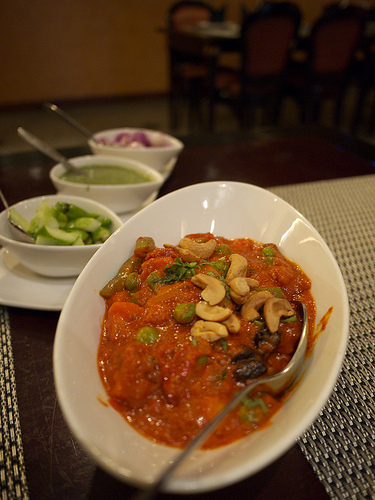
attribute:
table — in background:
[154, 2, 312, 129]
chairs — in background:
[162, 2, 373, 135]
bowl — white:
[48, 178, 343, 466]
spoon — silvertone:
[190, 268, 323, 465]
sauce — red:
[155, 350, 235, 415]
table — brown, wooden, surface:
[10, 150, 374, 477]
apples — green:
[6, 196, 113, 245]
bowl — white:
[0, 194, 125, 275]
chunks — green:
[16, 206, 111, 240]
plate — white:
[1, 244, 77, 307]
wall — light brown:
[0, 0, 163, 101]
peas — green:
[123, 273, 158, 291]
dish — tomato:
[149, 272, 247, 328]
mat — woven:
[213, 174, 365, 396]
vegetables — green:
[104, 235, 162, 298]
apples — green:
[21, 197, 92, 245]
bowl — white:
[16, 154, 370, 478]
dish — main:
[41, 175, 326, 470]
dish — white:
[148, 182, 314, 287]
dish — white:
[0, 243, 95, 308]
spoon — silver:
[136, 297, 317, 490]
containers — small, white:
[7, 115, 195, 281]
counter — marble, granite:
[23, 393, 57, 462]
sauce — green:
[52, 154, 159, 195]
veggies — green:
[8, 202, 111, 244]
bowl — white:
[88, 121, 195, 163]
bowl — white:
[44, 145, 172, 201]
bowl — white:
[3, 187, 125, 277]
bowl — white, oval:
[36, 163, 355, 499]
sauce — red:
[95, 232, 315, 450]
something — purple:
[91, 128, 170, 147]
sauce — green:
[55, 150, 169, 200]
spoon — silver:
[123, 289, 317, 498]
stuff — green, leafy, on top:
[140, 239, 247, 298]